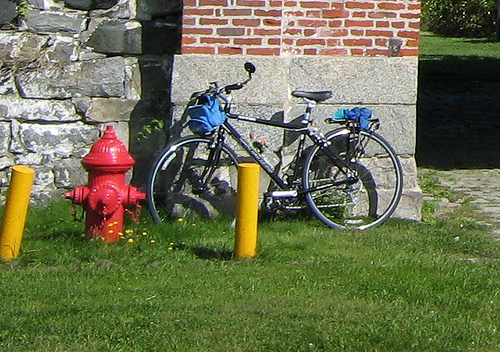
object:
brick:
[340, 37, 375, 48]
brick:
[323, 37, 340, 44]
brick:
[294, 37, 325, 47]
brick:
[199, 33, 231, 45]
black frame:
[220, 114, 310, 186]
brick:
[363, 25, 395, 39]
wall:
[170, 0, 425, 221]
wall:
[0, 0, 182, 212]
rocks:
[14, 55, 125, 98]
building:
[152, 0, 423, 223]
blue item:
[344, 105, 372, 129]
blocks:
[288, 55, 419, 107]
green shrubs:
[421, 0, 499, 40]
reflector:
[156, 132, 176, 169]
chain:
[99, 205, 109, 230]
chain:
[125, 203, 142, 224]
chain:
[65, 200, 85, 222]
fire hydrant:
[61, 122, 147, 245]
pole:
[231, 162, 261, 259]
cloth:
[332, 106, 345, 121]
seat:
[288, 91, 333, 107]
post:
[0, 166, 38, 261]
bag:
[183, 90, 227, 136]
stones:
[79, 17, 159, 56]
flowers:
[144, 237, 155, 245]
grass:
[0, 198, 499, 351]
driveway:
[417, 166, 499, 232]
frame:
[195, 105, 371, 216]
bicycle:
[148, 62, 403, 232]